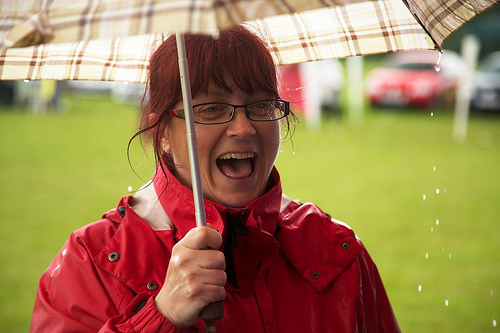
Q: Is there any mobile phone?
A: No, there are no cell phones.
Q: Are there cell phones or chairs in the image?
A: No, there are no cell phones or chairs.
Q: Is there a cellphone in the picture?
A: No, there are no cell phones.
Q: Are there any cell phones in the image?
A: No, there are no cell phones.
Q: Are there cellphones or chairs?
A: No, there are no cellphones or chairs.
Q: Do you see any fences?
A: No, there are no fences.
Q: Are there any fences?
A: No, there are no fences.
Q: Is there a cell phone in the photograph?
A: No, there are no cell phones.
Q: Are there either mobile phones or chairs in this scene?
A: No, there are no mobile phones or chairs.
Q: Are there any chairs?
A: No, there are no chairs.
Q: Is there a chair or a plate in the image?
A: No, there are no chairs or plates.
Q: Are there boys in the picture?
A: No, there are no boys.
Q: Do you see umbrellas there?
A: Yes, there is an umbrella.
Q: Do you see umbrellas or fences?
A: Yes, there is an umbrella.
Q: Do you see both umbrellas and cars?
A: Yes, there are both an umbrella and a car.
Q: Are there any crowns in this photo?
A: No, there are no crowns.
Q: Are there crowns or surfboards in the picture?
A: No, there are no crowns or surfboards.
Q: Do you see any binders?
A: No, there are no binders.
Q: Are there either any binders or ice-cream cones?
A: No, there are no binders or ice-cream cones.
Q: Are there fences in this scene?
A: No, there are no fences.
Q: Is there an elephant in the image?
A: No, there are no elephants.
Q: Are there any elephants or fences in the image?
A: No, there are no elephants or fences.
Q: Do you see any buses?
A: No, there are no buses.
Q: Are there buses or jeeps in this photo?
A: No, there are no buses or jeeps.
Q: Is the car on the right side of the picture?
A: Yes, the car is on the right of the image.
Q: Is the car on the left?
A: No, the car is on the right of the image.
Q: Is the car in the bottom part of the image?
A: No, the car is in the top of the image.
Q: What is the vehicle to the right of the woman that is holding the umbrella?
A: The vehicle is a car.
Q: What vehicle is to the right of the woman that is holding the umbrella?
A: The vehicle is a car.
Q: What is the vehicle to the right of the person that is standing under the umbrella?
A: The vehicle is a car.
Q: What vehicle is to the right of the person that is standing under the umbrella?
A: The vehicle is a car.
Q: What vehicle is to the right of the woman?
A: The vehicle is a car.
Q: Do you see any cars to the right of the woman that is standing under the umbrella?
A: Yes, there is a car to the right of the woman.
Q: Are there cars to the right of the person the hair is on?
A: Yes, there is a car to the right of the woman.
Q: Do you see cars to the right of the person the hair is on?
A: Yes, there is a car to the right of the woman.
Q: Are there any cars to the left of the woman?
A: No, the car is to the right of the woman.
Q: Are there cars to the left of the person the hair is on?
A: No, the car is to the right of the woman.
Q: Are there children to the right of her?
A: No, there is a car to the right of the woman.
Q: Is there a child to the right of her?
A: No, there is a car to the right of the woman.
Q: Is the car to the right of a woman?
A: Yes, the car is to the right of a woman.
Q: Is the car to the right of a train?
A: No, the car is to the right of a woman.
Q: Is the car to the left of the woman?
A: No, the car is to the right of the woman.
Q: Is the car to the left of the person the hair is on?
A: No, the car is to the right of the woman.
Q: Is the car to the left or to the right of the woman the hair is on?
A: The car is to the right of the woman.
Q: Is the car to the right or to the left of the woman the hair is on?
A: The car is to the right of the woman.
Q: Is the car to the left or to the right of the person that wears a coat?
A: The car is to the right of the woman.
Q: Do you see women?
A: Yes, there is a woman.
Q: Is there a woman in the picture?
A: Yes, there is a woman.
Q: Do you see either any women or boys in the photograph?
A: Yes, there is a woman.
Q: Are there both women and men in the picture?
A: No, there is a woman but no men.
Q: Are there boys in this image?
A: No, there are no boys.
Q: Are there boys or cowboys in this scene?
A: No, there are no boys or cowboys.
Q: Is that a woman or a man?
A: That is a woman.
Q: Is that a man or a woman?
A: That is a woman.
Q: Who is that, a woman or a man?
A: That is a woman.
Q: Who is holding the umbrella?
A: The woman is holding the umbrella.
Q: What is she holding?
A: The woman is holding the umbrella.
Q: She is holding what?
A: The woman is holding the umbrella.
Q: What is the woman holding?
A: The woman is holding the umbrella.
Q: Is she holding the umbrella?
A: Yes, the woman is holding the umbrella.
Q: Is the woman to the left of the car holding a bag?
A: No, the woman is holding the umbrella.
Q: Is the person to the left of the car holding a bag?
A: No, the woman is holding the umbrella.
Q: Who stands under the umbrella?
A: The woman stands under the umbrella.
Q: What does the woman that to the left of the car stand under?
A: The woman stands under the umbrella.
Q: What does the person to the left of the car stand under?
A: The woman stands under the umbrella.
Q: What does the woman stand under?
A: The woman stands under the umbrella.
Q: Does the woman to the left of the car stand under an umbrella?
A: Yes, the woman stands under an umbrella.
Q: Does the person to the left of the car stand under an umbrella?
A: Yes, the woman stands under an umbrella.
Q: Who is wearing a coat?
A: The woman is wearing a coat.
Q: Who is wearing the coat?
A: The woman is wearing a coat.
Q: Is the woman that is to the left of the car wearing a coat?
A: Yes, the woman is wearing a coat.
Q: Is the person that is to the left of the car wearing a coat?
A: Yes, the woman is wearing a coat.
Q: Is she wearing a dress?
A: No, the woman is wearing a coat.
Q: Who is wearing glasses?
A: The woman is wearing glasses.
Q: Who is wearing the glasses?
A: The woman is wearing glasses.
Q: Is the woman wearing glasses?
A: Yes, the woman is wearing glasses.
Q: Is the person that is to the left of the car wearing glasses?
A: Yes, the woman is wearing glasses.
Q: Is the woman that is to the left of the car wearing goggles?
A: No, the woman is wearing glasses.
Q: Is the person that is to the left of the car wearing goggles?
A: No, the woman is wearing glasses.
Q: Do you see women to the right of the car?
A: No, the woman is to the left of the car.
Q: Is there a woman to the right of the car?
A: No, the woman is to the left of the car.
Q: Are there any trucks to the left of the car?
A: No, there is a woman to the left of the car.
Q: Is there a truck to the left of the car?
A: No, there is a woman to the left of the car.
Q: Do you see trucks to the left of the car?
A: No, there is a woman to the left of the car.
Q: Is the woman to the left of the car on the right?
A: Yes, the woman is to the left of the car.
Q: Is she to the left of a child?
A: No, the woman is to the left of the car.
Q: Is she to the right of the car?
A: No, the woman is to the left of the car.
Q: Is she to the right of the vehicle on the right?
A: No, the woman is to the left of the car.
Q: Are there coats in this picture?
A: Yes, there is a coat.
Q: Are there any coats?
A: Yes, there is a coat.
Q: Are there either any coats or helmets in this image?
A: Yes, there is a coat.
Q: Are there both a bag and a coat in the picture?
A: No, there is a coat but no bags.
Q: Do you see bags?
A: No, there are no bags.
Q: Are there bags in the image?
A: No, there are no bags.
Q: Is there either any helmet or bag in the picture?
A: No, there are no bags or helmets.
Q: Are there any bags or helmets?
A: No, there are no bags or helmets.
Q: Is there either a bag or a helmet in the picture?
A: No, there are no bags or helmets.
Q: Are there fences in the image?
A: No, there are no fences.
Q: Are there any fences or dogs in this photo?
A: No, there are no fences or dogs.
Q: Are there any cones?
A: No, there are no cones.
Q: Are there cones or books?
A: No, there are no cones or books.